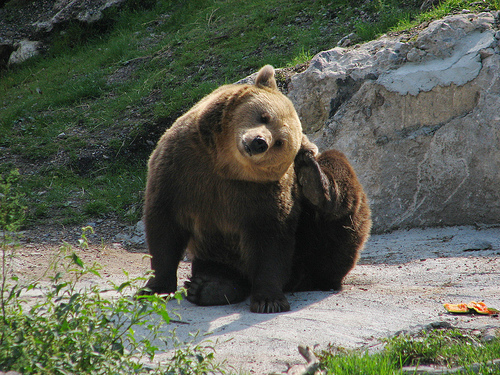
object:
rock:
[287, 17, 499, 235]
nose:
[252, 137, 268, 151]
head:
[216, 64, 317, 181]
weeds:
[134, 161, 148, 198]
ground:
[432, 230, 500, 263]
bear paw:
[251, 291, 290, 314]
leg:
[184, 231, 250, 307]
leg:
[137, 178, 195, 299]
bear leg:
[295, 146, 371, 261]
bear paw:
[131, 284, 177, 302]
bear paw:
[182, 272, 243, 305]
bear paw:
[292, 149, 331, 210]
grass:
[75, 48, 129, 69]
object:
[442, 300, 497, 319]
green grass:
[0, 151, 101, 213]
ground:
[0, 260, 473, 371]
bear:
[133, 65, 376, 314]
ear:
[255, 64, 277, 85]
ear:
[300, 140, 319, 161]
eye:
[259, 114, 270, 123]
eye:
[273, 140, 284, 148]